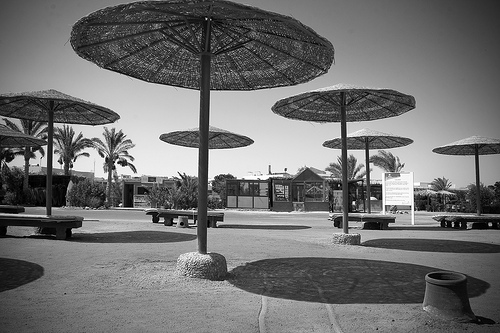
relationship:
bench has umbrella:
[430, 205, 498, 237] [431, 131, 498, 167]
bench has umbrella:
[327, 205, 395, 230] [265, 80, 418, 121]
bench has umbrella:
[150, 208, 225, 228] [162, 122, 256, 149]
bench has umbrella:
[150, 208, 225, 228] [70, 3, 341, 84]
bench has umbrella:
[0, 210, 86, 235] [0, 81, 122, 129]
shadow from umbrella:
[227, 254, 495, 310] [70, 3, 341, 84]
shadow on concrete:
[227, 254, 495, 310] [0, 208, 499, 332]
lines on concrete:
[253, 258, 355, 330] [0, 208, 499, 332]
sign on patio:
[381, 171, 415, 228] [0, 206, 497, 328]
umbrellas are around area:
[21, 32, 482, 247] [1, 210, 498, 330]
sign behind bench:
[381, 171, 415, 228] [328, 212, 395, 227]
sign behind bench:
[381, 171, 415, 228] [147, 209, 225, 228]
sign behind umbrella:
[381, 171, 415, 228] [430, 134, 497, 214]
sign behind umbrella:
[381, 171, 415, 228] [323, 125, 415, 212]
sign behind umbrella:
[381, 171, 415, 228] [271, 81, 414, 236]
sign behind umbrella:
[381, 171, 415, 228] [70, 1, 332, 254]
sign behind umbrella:
[381, 171, 415, 228] [2, 88, 123, 217]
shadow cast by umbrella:
[103, 226, 195, 245] [70, 3, 341, 84]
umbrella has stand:
[61, 2, 341, 111] [170, 250, 232, 283]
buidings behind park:
[272, 167, 350, 212] [13, 201, 498, 331]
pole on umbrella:
[196, 22, 213, 252] [68, 22, 295, 84]